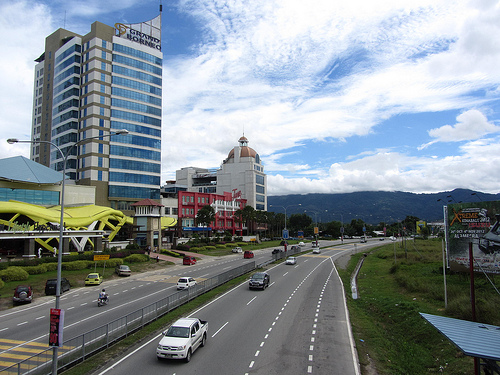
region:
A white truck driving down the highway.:
[141, 311, 228, 365]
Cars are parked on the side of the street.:
[83, 263, 143, 287]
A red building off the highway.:
[181, 190, 245, 242]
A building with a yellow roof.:
[3, 191, 140, 240]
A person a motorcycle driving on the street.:
[91, 285, 136, 313]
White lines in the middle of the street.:
[294, 270, 324, 374]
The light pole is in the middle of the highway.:
[12, 137, 74, 363]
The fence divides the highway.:
[78, 293, 188, 321]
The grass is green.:
[376, 256, 436, 371]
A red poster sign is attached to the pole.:
[31, 299, 80, 354]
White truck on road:
[156, 303, 217, 370]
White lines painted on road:
[251, 284, 388, 373]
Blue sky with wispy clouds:
[261, 6, 458, 214]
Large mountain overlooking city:
[294, 155, 414, 207]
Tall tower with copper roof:
[205, 101, 294, 229]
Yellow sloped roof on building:
[2, 183, 162, 248]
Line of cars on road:
[144, 230, 333, 345]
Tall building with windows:
[29, 26, 220, 176]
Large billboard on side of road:
[431, 188, 498, 285]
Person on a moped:
[85, 285, 120, 310]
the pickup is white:
[162, 311, 214, 361]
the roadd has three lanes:
[228, 297, 339, 353]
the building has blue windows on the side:
[42, 34, 160, 197]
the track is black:
[245, 265, 273, 293]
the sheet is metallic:
[422, 310, 496, 359]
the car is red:
[175, 253, 203, 267]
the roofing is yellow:
[2, 194, 134, 229]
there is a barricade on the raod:
[148, 284, 228, 304]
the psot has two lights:
[28, 139, 130, 334]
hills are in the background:
[322, 186, 447, 209]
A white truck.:
[152, 310, 208, 360]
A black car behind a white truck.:
[246, 265, 266, 290]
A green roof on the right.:
[418, 311, 499, 362]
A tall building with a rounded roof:
[215, 130, 265, 215]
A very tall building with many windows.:
[27, 5, 162, 240]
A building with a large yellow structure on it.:
[0, 150, 130, 255]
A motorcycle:
[90, 285, 105, 300]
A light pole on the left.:
[0, 125, 125, 370]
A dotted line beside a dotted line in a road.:
[245, 246, 335, 371]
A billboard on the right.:
[438, 203, 498, 274]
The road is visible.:
[277, 279, 334, 373]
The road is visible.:
[268, 328, 300, 360]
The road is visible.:
[211, 270, 306, 371]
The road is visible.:
[234, 238, 298, 352]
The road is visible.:
[245, 303, 377, 373]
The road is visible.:
[264, 308, 319, 373]